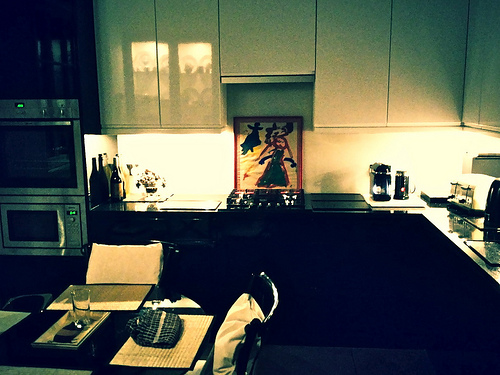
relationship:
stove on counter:
[222, 187, 300, 208] [106, 186, 473, 218]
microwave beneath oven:
[2, 203, 83, 248] [2, 102, 87, 194]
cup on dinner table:
[69, 281, 94, 323] [0, 286, 219, 374]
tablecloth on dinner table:
[107, 307, 214, 367] [8, 280, 219, 374]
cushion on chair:
[80, 240, 163, 287] [204, 276, 283, 371]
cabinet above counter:
[154, 0, 221, 128] [93, 182, 460, 220]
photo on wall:
[233, 116, 304, 194] [188, 49, 385, 224]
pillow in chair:
[219, 304, 254, 356] [255, 281, 282, 324]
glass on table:
[72, 292, 89, 303] [35, 184, 257, 366]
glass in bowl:
[72, 292, 89, 303] [34, 294, 109, 351]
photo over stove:
[228, 108, 307, 193] [218, 186, 312, 333]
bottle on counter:
[98, 154, 109, 200] [74, 89, 225, 303]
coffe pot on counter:
[367, 160, 393, 201] [92, 184, 499, 285]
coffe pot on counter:
[394, 167, 411, 199] [92, 184, 499, 285]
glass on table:
[65, 281, 95, 323] [4, 297, 216, 373]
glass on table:
[72, 292, 89, 303] [3, 307, 220, 374]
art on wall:
[241, 117, 328, 192] [121, 88, 464, 206]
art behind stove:
[241, 117, 328, 192] [222, 187, 300, 234]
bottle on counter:
[109, 157, 123, 202] [90, 193, 226, 213]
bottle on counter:
[88, 156, 103, 201] [90, 193, 226, 213]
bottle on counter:
[96, 153, 110, 198] [90, 193, 226, 213]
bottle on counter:
[102, 153, 112, 190] [90, 193, 226, 213]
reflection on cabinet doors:
[111, 30, 223, 130] [283, 12, 466, 157]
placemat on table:
[44, 281, 152, 313] [1, 268, 231, 373]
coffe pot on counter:
[369, 162, 391, 200] [319, 196, 431, 231]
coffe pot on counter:
[369, 162, 391, 200] [303, 191, 470, 216]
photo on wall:
[233, 116, 304, 194] [119, 139, 451, 211]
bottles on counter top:
[90, 150, 126, 203] [96, 187, 232, 214]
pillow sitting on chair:
[211, 292, 264, 374] [207, 265, 280, 373]